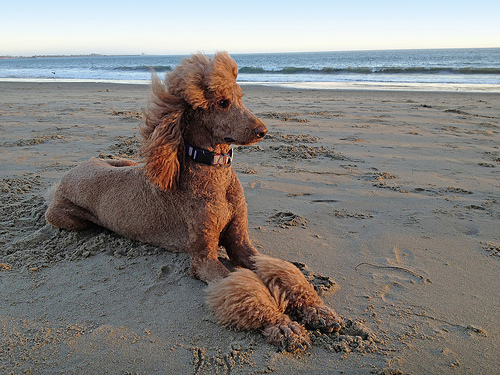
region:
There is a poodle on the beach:
[39, 52, 391, 343]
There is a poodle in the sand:
[42, 24, 376, 348]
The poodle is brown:
[36, 31, 368, 341]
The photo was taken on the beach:
[38, 30, 453, 367]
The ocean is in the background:
[40, 16, 490, 201]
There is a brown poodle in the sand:
[23, 30, 458, 366]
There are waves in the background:
[185, 29, 462, 321]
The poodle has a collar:
[119, 52, 319, 227]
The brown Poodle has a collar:
[62, 37, 329, 325]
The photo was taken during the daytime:
[45, 30, 430, 266]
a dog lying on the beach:
[45, 50, 350, 352]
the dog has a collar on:
[42, 50, 342, 350]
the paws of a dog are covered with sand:
[247, 296, 349, 361]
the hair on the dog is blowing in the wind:
[131, 46, 328, 342]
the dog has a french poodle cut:
[44, 47, 345, 349]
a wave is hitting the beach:
[0, 56, 496, 87]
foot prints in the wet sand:
[268, 196, 498, 346]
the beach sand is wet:
[2, 86, 494, 366]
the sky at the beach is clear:
[5, 0, 498, 96]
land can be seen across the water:
[1, 47, 153, 85]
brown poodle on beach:
[51, 53, 377, 338]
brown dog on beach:
[47, 54, 372, 349]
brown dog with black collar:
[47, 55, 339, 303]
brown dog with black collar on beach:
[49, 56, 351, 347]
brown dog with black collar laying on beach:
[51, 50, 361, 336]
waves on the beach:
[256, 55, 493, 91]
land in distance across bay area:
[1, 40, 151, 69]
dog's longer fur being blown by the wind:
[132, 41, 272, 195]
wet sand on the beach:
[273, 111, 479, 241]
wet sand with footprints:
[273, 104, 395, 237]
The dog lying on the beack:
[39, 44, 345, 353]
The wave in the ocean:
[107, 59, 495, 76]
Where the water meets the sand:
[0, 71, 495, 97]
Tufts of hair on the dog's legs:
[201, 251, 348, 351]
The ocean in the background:
[2, 43, 498, 90]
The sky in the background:
[2, 1, 496, 58]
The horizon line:
[2, 44, 499, 61]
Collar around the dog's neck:
[184, 137, 236, 169]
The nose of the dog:
[249, 118, 273, 147]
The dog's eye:
[217, 93, 232, 111]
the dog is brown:
[78, 85, 293, 300]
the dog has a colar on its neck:
[185, 142, 250, 169]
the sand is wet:
[331, 155, 426, 297]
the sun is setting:
[275, 15, 485, 40]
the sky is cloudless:
[65, 20, 460, 35]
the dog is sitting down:
[75, 96, 305, 297]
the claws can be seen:
[275, 305, 355, 345]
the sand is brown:
[338, 248, 476, 320]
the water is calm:
[333, 47, 485, 77]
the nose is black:
[244, 115, 298, 152]